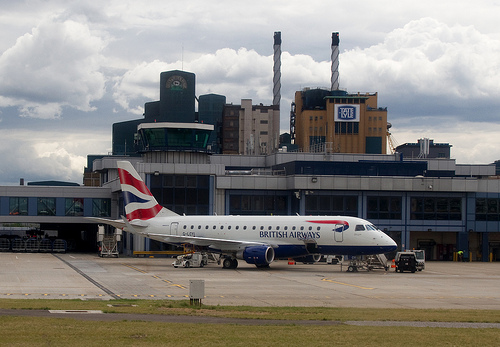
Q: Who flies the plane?
A: The pilot.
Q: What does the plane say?
A: British Airways.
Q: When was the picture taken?
A: In the day time.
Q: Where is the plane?
A: In front of the building.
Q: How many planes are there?
A: 1.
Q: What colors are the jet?
A: White, red and blue.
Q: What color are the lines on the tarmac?
A: Yellow.